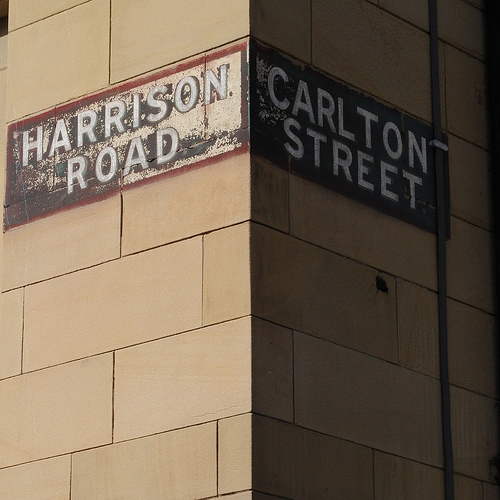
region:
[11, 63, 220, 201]
sign is for harrison road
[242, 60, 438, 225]
sign is for carlton street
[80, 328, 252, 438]
wall's pattern is tile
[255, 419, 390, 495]
this wall is in shadow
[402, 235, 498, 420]
pole on side of wall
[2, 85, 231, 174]
sign is painted on building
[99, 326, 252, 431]
square shape on tile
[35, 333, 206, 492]
sun reflected on building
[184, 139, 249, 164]
border of sign is red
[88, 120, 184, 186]
writing in white paint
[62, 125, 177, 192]
White word on black sign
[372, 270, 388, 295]
Black hole in tan wall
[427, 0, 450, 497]
Long wire down the wall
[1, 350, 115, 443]
Tan brick in wall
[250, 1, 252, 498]
Long sharp corner of building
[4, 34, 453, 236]
Large black sign with red outline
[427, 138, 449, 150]
Metal bracket in wall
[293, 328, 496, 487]
Long tan brick in wall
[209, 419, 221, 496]
Crack between bricks in wall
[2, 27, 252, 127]
Top red outline on sign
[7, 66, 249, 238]
sign on a brick building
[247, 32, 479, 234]
street sign on brick building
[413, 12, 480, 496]
steel pipe up a building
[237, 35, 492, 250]
a painted street sign on building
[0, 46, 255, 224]
painted street sign on a building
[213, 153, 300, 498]
edge of a building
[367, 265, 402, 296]
stain on a building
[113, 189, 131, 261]
gaps between a brick building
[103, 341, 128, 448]
gaps between a brick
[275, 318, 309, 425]
gaps between a brick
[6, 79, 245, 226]
road name on the side of the building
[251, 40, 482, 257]
street name on the side of the building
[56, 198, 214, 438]
side of the building is in the light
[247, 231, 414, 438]
side of building is in the shade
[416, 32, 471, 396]
black cord going down the wall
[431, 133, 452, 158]
clamp on the black cord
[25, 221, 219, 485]
building is made of large bricks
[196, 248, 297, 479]
corner of the building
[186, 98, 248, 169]
black paint is fading away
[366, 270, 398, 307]
hole in the wall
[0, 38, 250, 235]
Street sign printed onto building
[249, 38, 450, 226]
Street sign printed onto building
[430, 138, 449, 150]
Metal bracket on pole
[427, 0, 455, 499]
Long pole along street sign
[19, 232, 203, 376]
Beige brick wall below street sign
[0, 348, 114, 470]
Beige brick wall below street sign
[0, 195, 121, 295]
Beige brick wall below street sign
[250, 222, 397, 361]
Beige brick wall below street sign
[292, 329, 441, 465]
Beige brick wall below street sign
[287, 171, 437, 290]
Beige brick wall below street sign